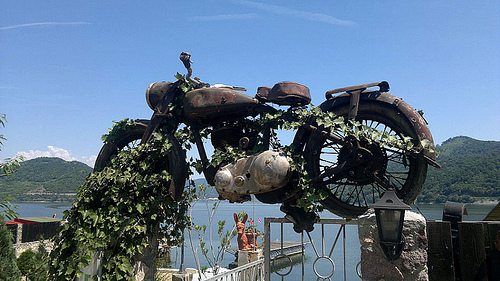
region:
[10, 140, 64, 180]
This is a hill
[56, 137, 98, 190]
This is a hill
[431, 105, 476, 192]
This is a hill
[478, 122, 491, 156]
This is a hill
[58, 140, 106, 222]
This is a hill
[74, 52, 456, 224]
This is an old motorbike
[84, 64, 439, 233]
A rusted old motorcycle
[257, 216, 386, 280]
A small stone fence by the motorcycle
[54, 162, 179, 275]
Green leaves growing on the bike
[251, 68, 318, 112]
The old leather seat of the bike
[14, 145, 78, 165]
Fluffy white clouds in the sky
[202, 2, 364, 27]
Thin, wispy white clouds in the sky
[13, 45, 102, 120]
A patch of open blue sky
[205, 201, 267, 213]
The blue water looks calm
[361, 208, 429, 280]
A short stone pillar by the bike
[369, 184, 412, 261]
A black lamp under the bike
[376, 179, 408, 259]
old fashioned lantern style exterior light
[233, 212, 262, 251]
clay donkey flower pot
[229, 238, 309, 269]
small pontoon dock on lake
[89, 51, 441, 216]
decorative entry archway made with old motorcycle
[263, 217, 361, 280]
metal gate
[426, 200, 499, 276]
wooden fence with metal fitting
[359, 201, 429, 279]
concrete and stone gate post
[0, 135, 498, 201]
hills bordering lake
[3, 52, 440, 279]
ivy growing on motorcycle archway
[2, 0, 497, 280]
iconic rusty motorcycle arch seen against blue sky and lake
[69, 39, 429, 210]
a motorcycle on display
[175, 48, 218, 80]
the handles of a motorcycle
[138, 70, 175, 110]
the headlight of a motorcycle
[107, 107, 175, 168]
the front wheel of a motorcycle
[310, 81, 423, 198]
the back wheel of a motorcycle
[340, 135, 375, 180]
the wheel center of a motorcycle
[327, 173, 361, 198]
the spokes of a motorcycle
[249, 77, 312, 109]
the seat of a motorcycle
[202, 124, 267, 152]
the gears of a motorcycle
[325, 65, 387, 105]
the back shelf of a motorcycle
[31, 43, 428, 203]
old motorcycle on top of a fence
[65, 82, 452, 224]
ivy growing on the motorcycle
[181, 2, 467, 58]
blue sky barely streaked with clouds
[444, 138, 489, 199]
tree covered mountain in the distance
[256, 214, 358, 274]
white metal gate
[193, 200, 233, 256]
water out beyond the gate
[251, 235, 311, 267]
building over the water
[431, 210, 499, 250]
wooden fence by the post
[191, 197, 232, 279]
limbs from a tree